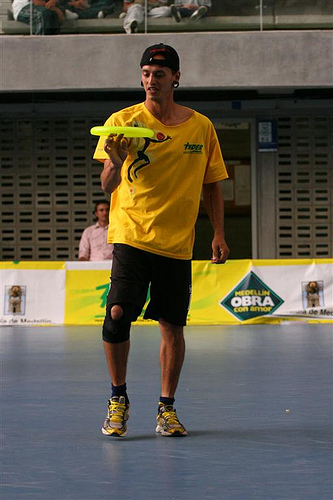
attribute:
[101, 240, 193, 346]
shorts — black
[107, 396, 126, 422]
lace — yellow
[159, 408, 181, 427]
lace — yellow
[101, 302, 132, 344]
brace — black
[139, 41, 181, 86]
hat — backwards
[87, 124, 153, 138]
frisbee — yellow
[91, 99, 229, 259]
shirt — yellow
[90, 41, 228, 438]
man — standing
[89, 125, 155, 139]
frisbee — neon green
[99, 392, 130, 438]
shoe — yellow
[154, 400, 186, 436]
shoe — yellow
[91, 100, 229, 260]
t-shirt — yellow, short sleeve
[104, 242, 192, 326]
shorts — black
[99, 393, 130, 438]
tennis shoe — black, white, yellow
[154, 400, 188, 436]
tennis shoe — yellow, white, black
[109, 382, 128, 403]
sock — short, blue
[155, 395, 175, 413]
sock — blue, short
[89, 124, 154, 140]
frisbee — bright yellow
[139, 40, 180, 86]
cap — black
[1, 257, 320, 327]
stadium banner — long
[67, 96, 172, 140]
frisbee — yellow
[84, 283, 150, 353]
brace — black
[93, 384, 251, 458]
shoes — grey, yellow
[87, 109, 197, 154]
frisbee — yellow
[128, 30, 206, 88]
cap — black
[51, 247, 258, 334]
banner — yellow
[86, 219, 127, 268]
man — standing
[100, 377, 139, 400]
sock — black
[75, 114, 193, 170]
frisbee — yellow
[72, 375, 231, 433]
shoes — yellow, grey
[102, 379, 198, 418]
socks — blue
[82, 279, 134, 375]
brace — black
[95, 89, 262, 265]
shirt — yellow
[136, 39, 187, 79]
hat — black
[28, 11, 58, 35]
jeans — blue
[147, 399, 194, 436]
shoe — yellow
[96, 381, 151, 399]
sock — black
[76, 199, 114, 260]
man — BACKGROUND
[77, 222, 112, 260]
shirt — PINK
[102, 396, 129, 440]
shoe — YELLOW